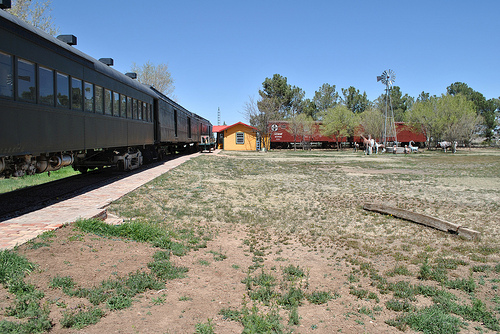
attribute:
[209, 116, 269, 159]
building — red, yellow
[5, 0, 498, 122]
sky — blue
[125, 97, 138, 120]
window — glass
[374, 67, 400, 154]
weather vane — tall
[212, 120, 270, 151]
house — orange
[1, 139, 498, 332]
sand — brown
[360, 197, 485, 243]
object — silver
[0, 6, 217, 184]
train — large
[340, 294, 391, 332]
pebbles — tiny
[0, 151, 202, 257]
path — clear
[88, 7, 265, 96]
clouds — white